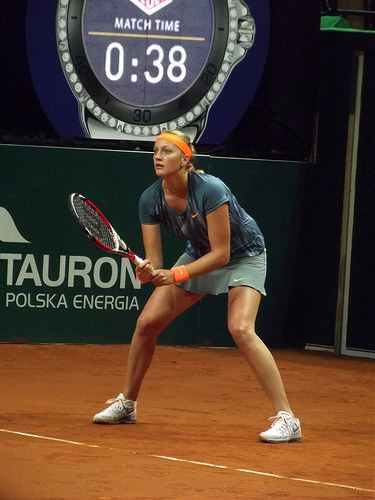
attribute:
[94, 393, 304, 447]
sneakers — white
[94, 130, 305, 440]
woman — playing, holding, blonde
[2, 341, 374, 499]
ground — brown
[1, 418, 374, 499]
line — white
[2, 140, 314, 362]
barrier — green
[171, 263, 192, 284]
band — orange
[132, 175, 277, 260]
shirt — grey, gray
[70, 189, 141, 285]
bat — red, black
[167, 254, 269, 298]
skirt — grey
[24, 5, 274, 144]
bilboard — large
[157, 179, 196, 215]
chain — gold